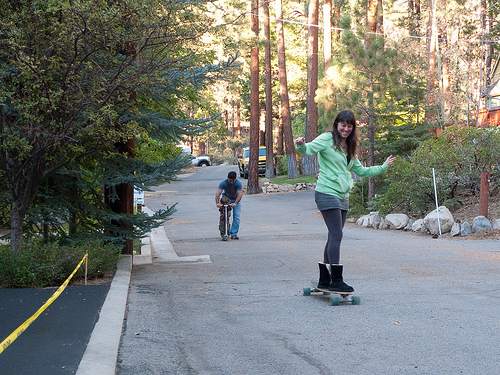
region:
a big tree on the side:
[1, 2, 213, 254]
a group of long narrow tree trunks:
[238, 40, 325, 190]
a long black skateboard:
[301, 280, 353, 305]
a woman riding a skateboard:
[296, 111, 393, 306]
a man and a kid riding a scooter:
[213, 172, 248, 244]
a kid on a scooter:
[216, 197, 236, 239]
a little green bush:
[371, 132, 496, 235]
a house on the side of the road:
[472, 45, 499, 145]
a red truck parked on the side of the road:
[232, 147, 278, 174]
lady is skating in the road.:
[288, 96, 377, 325]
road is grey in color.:
[203, 318, 277, 356]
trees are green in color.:
[31, 48, 112, 150]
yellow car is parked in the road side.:
[237, 142, 283, 184]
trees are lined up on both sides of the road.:
[41, 39, 458, 181]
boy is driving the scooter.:
[216, 197, 236, 240]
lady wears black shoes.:
[314, 260, 387, 300]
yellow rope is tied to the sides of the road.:
[21, 253, 103, 335]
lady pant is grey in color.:
[316, 194, 356, 261]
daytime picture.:
[114, 37, 413, 292]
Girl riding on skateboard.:
[283, 111, 413, 316]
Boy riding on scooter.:
[203, 164, 251, 246]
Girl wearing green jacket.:
[293, 128, 391, 198]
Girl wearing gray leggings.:
[316, 210, 363, 267]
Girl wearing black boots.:
[311, 258, 358, 300]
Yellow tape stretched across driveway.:
[4, 256, 96, 364]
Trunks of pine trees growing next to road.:
[246, 55, 322, 191]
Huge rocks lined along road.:
[366, 208, 495, 240]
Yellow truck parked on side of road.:
[233, 146, 278, 178]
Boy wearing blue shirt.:
[212, 177, 247, 197]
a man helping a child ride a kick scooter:
[204, 164, 254, 251]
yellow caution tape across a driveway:
[0, 251, 100, 371]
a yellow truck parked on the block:
[226, 141, 281, 175]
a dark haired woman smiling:
[289, 107, 409, 294]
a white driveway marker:
[420, 161, 451, 238]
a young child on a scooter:
[214, 196, 236, 241]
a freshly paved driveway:
[1, 280, 113, 373]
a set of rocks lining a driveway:
[354, 206, 498, 238]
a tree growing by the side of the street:
[4, 44, 212, 258]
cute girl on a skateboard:
[289, 107, 398, 308]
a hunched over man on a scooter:
[214, 167, 247, 242]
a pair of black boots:
[314, 258, 354, 297]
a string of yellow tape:
[1, 250, 90, 354]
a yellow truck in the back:
[235, 142, 281, 180]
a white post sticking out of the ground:
[429, 163, 446, 239]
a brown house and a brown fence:
[466, 45, 498, 132]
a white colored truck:
[165, 140, 215, 171]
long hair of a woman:
[328, 105, 362, 165]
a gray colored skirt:
[310, 183, 353, 218]